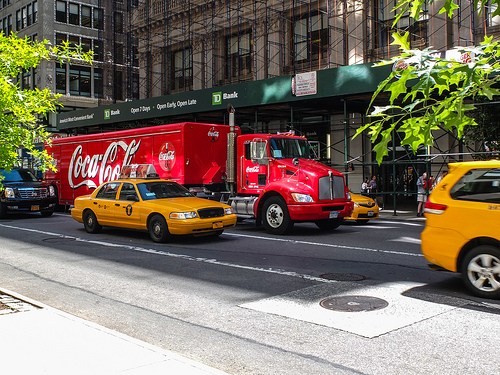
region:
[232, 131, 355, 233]
red truck next to taxi cab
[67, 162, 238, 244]
taxi cab next to red truck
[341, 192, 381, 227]
taxi cab next to red truck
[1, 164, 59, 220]
black suv next to red truck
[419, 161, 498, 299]
yellow taxi in front of yellow taxi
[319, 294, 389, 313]
black manhole next to taxi cab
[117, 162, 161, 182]
advertisement on top of taxi cab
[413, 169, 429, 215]
person standing on sidewalk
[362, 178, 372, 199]
person standing on sidewalk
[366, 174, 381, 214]
person standing on sidewalk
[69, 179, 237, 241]
A yellow taxi or cab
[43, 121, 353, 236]
A large red coca cola truck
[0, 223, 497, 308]
A faded white line in street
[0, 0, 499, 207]
A building in the distance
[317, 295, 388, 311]
A metal man hole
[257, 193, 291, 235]
A large black wheel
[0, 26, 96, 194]
A tree with green leaves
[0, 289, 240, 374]
A sidewalk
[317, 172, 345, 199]
Large grill of truck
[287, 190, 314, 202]
Headlight of a truck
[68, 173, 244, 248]
yellow taxi in the middle lane of traffic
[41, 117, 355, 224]
large red Coca-Cola semi truck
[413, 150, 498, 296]
back end of a yellow SUV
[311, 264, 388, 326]
two round man holes in the street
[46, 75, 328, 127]
long green sign on the TD Bank building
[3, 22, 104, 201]
very green leaves from a tree nearby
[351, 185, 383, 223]
very front end of a yellow taxi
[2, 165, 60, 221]
front end of a black SUV behind the taxi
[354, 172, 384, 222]
pedestrians walking on the sidewalk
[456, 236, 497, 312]
black tire on the back of the SUV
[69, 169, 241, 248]
A yellow taxi cab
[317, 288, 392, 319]
A pothole on the ground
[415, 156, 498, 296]
The back of a yellow car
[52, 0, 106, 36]
Four windows on a building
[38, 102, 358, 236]
A long red truck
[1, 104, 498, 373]
Vehicles are on the road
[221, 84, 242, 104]
The word "Bank" on a green sign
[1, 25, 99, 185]
Green leaves of a tree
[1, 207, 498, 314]
White lines on the street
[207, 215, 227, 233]
A yellow license plate